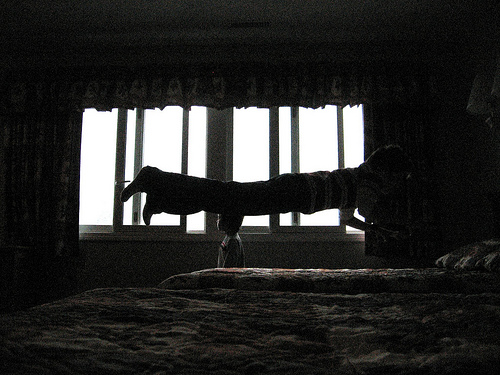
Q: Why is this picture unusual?
A: Man appears to be flying over furnitue.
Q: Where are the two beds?
A: Next to each other.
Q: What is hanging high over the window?
A: Curatin valance.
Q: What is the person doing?
A: Jumping.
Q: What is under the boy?
A: A bed.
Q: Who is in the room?
A: Two boys.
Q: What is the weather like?
A: Overcast.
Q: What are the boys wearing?
A: Clothes.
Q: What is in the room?
A: Two beds.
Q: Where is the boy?
A: Bouncing on the bed.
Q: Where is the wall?
A: On opposite side of room.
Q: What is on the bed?
A: Floral blanket.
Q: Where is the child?
A: Leaping into bed.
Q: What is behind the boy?
A: A window.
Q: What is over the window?
A: A valance.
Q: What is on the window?
A: Curtains.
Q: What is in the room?
A: Two beds.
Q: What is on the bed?
A: Bedspread.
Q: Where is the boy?
A: Over bed.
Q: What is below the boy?
A: Bed.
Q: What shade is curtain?
A: Dark.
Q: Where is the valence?
A: On window.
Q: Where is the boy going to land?
A: Bed.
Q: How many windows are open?
A: Two.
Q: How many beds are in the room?
A: Two.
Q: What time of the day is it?
A: Daytime.